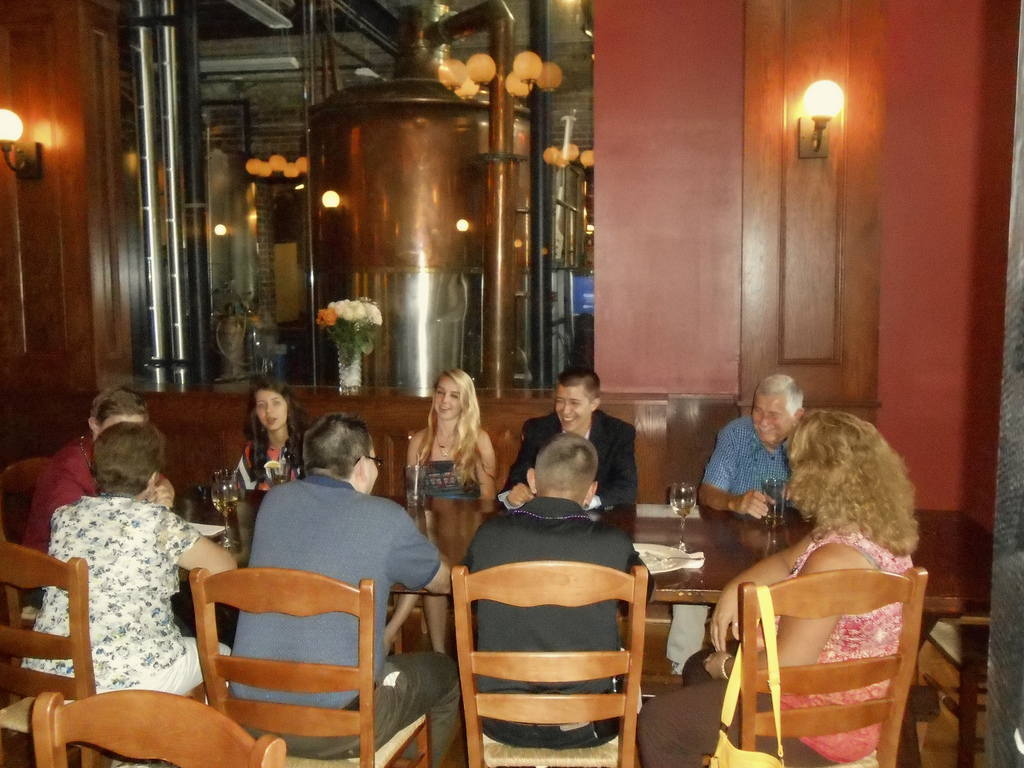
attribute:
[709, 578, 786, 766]
purse — yellow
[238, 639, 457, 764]
pants — gray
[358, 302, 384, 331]
flower — white, orange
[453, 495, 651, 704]
jacket — shiny, black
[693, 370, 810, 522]
man — laughing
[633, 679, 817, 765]
pants — brown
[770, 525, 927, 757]
top — pink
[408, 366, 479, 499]
hair — blonde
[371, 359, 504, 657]
woman — young 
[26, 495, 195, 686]
shirt — floral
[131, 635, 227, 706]
pants — white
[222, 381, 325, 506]
woman — young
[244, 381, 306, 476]
hair — long , wavy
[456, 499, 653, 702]
sweater — black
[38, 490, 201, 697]
shirt — white, black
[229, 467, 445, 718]
shirt — blue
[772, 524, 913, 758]
top — red, white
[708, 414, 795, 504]
shirt — blue 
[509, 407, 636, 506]
jacket — black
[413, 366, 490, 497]
hair — long, blond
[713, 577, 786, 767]
bag — Yellow 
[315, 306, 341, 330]
flower — white, pink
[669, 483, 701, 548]
glass — empty